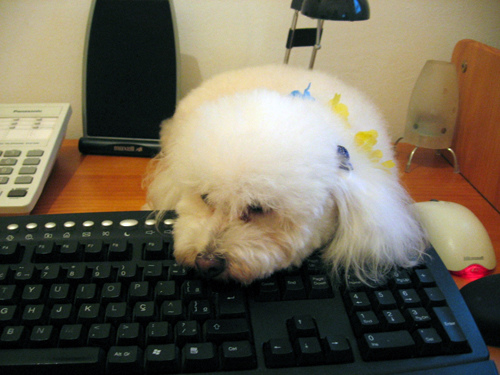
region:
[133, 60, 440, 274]
A fluffy white dog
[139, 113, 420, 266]
The dog's head is on the keyboard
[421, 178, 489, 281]
White computer mouse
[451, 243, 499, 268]
The mouse is made by Microsoft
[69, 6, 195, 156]
A computer speaker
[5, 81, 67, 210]
A landline telephone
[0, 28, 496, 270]
The objects are sitting on a brown desk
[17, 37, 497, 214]
The desk is made of wood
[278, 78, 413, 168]
The dog is wearing a blue and yellow collar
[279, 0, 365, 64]
Desk lamp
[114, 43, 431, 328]
dog is on the keys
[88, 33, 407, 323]
a small poodle dog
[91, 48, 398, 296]
the dog is white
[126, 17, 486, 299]
the dog has yellow and blue flowers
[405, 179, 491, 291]
the mouse is white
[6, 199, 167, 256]
silver buttons on keyboard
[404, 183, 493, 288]
the light is red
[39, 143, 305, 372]
the keys are black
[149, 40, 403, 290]
the dog's nose is black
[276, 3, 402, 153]
a lamp behind the dog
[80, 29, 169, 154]
black speakers on a desk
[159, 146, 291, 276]
white face of a dog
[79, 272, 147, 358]
black buttons on a keyboard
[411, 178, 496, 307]
white mouse with a red light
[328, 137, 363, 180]
purple bow on a dog's ear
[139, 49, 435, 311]
whit dog resting on a keyboard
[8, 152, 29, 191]
grey bottons on a telephone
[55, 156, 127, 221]
wooden desk top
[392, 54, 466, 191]
clear frosted table lamp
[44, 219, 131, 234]
silver buttons on a black keyboard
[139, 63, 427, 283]
A white dog laying down.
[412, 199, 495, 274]
A white mouse.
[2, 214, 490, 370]
A black keyboard.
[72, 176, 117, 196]
Part of the brown table.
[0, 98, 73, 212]
Part of a white telephone.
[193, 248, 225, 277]
The dog's black nose.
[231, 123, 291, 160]
The dog's white fluffy fur.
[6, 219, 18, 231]
A small silver button.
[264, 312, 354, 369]
Four arrow keys on the keyboard.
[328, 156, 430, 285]
The dog's white ear.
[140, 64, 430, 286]
small very fluffy white dog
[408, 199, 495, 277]
white Microsoft optical mouse with red light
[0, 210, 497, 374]
black standard keyboard with extra function keys along the top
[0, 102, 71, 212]
old looking beige panasonic telephone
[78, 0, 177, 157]
black computer speaker is out of focus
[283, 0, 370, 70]
telescoping hooded desk lamp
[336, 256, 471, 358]
keyboard number pad partially covered with fluffy fur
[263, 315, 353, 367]
up, down, right, left directional keys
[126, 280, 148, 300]
black key with white letter P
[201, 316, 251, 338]
long black right side shift key